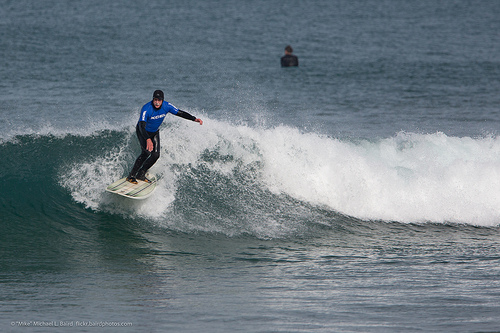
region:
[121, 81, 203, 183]
man in wet suit surfing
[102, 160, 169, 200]
green and white striped surfboard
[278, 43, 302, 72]
man floating in ocean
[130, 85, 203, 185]
black and blue wet suit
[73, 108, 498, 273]
white foamy crest of wave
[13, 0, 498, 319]
blue ocean water on sunny day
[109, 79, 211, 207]
man wearing black hat and surfing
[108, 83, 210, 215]
man with arm extended on white surfboard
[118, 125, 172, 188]
black shiny wet suit pants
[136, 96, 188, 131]
blue shirt with white writing and stripe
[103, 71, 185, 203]
man surfing on wave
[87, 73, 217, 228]
man surfing down wave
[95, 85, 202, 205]
man surfing on face of wave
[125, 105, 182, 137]
blue rashguard on top of man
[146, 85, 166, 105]
black hoodie on man's head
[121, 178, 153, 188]
black booties on man's feet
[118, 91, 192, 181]
man wearing black full suit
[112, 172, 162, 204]
white long board beneath man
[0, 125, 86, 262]
unbroken face of a wave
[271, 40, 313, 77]
man sitting on surf board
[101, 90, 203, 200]
man in ocean surfing the wave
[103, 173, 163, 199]
surf board cutting throug wave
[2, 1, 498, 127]
ocean of water in the background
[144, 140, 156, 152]
man hand in front helping him balance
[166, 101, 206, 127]
mans arm in back helping him balance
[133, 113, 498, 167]
crest of the wave man is on top of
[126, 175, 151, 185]
man feet on surf board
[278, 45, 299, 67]
person in background standing in ocean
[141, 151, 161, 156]
man knees bent to ride surf board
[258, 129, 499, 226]
white top part of wave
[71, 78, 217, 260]
the man is surfing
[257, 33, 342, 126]
a man standing in the water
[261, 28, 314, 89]
a man standing in the water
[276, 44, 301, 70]
a person in the water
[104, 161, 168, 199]
a white surfboard with stripes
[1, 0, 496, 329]
the ocean water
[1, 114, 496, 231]
a wave in the ocean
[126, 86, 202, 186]
a man riding a surfboard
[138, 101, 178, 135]
a blue shirt on a man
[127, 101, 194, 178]
a black wetsuit on a man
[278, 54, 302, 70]
a black shirt on a person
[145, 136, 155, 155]
a man's bare hand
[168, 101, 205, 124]
an arm held out